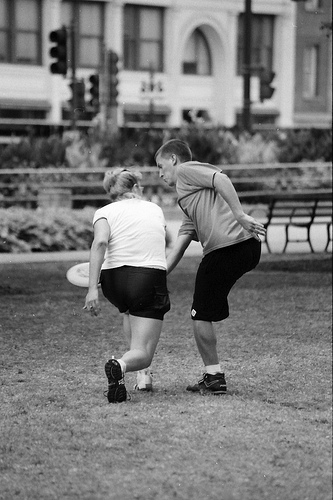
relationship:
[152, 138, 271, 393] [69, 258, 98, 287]
man plays frisbee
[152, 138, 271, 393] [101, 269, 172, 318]
man wear short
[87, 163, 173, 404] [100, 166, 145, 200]
woman has hair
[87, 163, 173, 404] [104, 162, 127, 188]
woman has ponytail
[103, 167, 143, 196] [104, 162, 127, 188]
blonde hair in ponytail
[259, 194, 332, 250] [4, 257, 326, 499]
bench by field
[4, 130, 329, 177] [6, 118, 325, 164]
bushes along roadway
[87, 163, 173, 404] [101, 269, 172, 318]
woman wears short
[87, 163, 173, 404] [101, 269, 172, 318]
woman wears short short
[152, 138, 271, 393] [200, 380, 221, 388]
man wears nike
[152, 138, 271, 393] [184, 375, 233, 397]
man wears shoe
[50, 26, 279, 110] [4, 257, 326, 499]
stoplights behind field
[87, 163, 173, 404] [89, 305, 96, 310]
woman wears ring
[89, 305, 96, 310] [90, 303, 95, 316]
ring on finger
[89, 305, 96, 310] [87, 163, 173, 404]
ring on woman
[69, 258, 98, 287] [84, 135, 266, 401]
frisbee playing people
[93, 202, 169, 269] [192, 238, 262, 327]
white and black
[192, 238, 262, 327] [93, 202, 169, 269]
black and white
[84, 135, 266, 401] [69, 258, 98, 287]
persons disputing a frisbee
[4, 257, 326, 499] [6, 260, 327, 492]
field covered with grass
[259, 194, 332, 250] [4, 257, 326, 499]
bench on field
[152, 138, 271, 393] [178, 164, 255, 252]
man wears a t-shirt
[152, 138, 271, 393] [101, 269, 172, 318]
man wears short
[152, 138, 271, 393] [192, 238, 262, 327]
man wears black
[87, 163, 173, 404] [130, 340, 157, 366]
woman has right knee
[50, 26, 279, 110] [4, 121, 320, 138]
lights on street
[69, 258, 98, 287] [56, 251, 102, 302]
frisbee in air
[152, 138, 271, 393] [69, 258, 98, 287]
man and woman playing frisbee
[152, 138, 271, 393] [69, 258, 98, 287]
man and playing frisbee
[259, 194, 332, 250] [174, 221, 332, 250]
bench in sidewalk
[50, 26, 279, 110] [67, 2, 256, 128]
lights attached to poles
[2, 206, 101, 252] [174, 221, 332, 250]
bushes in pathway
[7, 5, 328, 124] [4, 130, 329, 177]
buildings are behind bushes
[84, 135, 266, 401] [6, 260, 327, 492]
people playing in grass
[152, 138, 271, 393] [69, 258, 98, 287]
man playing frisbee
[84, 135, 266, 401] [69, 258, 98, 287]
people playing frisbee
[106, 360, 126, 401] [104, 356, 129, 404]
sole of a sneaker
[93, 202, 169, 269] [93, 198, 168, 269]
white t shirt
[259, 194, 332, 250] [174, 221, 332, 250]
bench on a sidewalk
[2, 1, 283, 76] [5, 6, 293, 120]
windows on building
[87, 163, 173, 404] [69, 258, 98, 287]
woman playing frisbee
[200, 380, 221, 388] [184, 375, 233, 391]
nike black shoe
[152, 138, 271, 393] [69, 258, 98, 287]
man reaching for frisbee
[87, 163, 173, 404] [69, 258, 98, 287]
woman playing with frisbee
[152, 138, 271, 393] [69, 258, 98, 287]
man playing with frisbee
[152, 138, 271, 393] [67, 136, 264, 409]
man and woman playing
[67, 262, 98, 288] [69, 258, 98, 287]
white flying frisbee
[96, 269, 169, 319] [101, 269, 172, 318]
pair of short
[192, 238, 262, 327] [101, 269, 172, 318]
black pair of short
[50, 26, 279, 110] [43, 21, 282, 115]
lights out of focus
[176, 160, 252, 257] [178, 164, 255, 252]
grey striped shirt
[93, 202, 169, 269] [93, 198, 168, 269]
white plain shirt